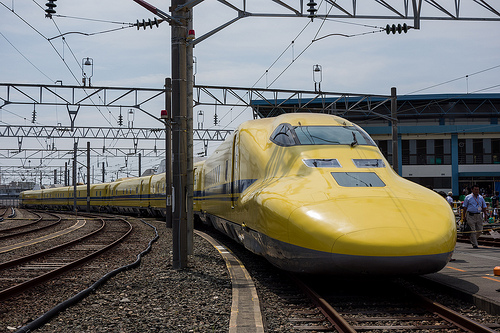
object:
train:
[18, 108, 458, 276]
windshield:
[289, 125, 373, 147]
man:
[460, 184, 487, 248]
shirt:
[461, 191, 488, 213]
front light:
[302, 155, 341, 168]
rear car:
[148, 162, 205, 220]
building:
[251, 92, 497, 220]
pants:
[464, 211, 486, 246]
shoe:
[470, 244, 480, 251]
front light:
[354, 157, 387, 170]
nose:
[258, 166, 459, 266]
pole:
[162, 4, 200, 274]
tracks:
[4, 207, 496, 332]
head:
[471, 184, 483, 197]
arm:
[458, 192, 470, 221]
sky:
[4, 5, 499, 193]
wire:
[57, 8, 139, 29]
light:
[160, 108, 168, 121]